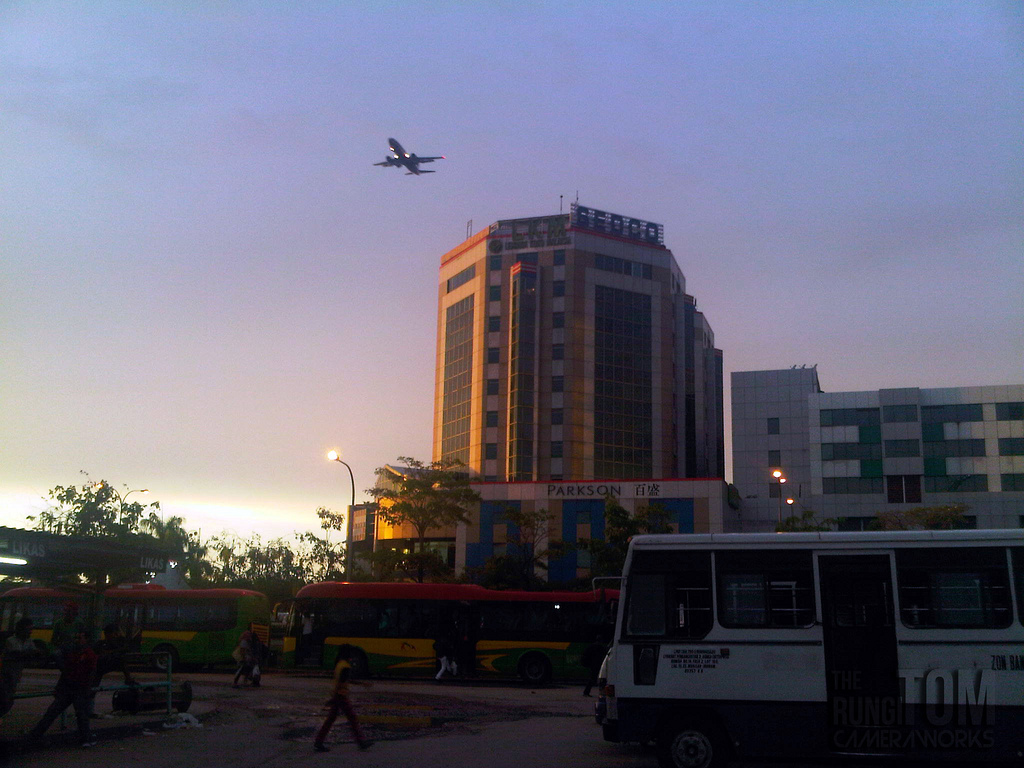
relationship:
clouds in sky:
[3, 1, 1021, 501] [0, 3, 1020, 604]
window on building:
[869, 409, 882, 426] [415, 187, 737, 501]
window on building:
[856, 408, 872, 424] [415, 187, 737, 501]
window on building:
[841, 409, 855, 425] [415, 187, 737, 501]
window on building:
[833, 409, 847, 425] [415, 187, 737, 501]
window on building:
[818, 408, 832, 427] [415, 187, 737, 501]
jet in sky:
[375, 136, 446, 175] [0, 3, 1020, 604]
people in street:
[267, 639, 354, 762] [0, 678, 621, 763]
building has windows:
[708, 344, 1022, 559] [806, 399, 1010, 490]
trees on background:
[55, 470, 336, 583] [7, 499, 381, 560]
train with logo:
[608, 507, 1003, 717] [4, 520, 177, 572]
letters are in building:
[491, 215, 680, 244] [400, 207, 775, 450]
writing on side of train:
[521, 467, 645, 519] [608, 507, 1003, 717]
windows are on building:
[930, 385, 994, 495] [730, 356, 1020, 542]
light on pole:
[327, 451, 338, 460] [320, 440, 357, 587]